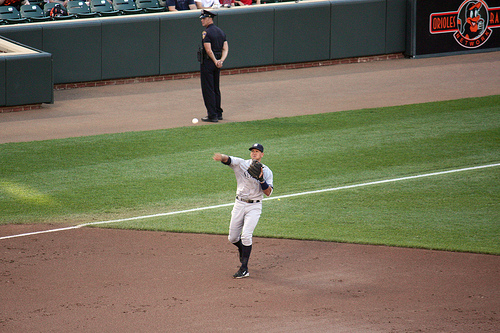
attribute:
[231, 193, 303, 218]
belt — black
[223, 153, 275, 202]
shirt — grey, black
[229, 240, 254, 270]
socks — black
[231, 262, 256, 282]
shoe — black, white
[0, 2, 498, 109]
fence — green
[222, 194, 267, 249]
pants — white